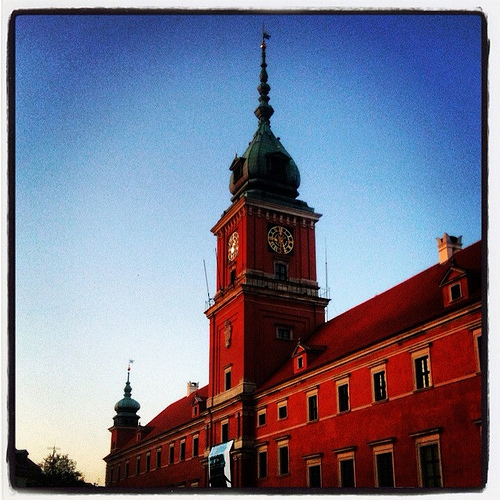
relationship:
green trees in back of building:
[37, 445, 85, 491] [102, 14, 486, 493]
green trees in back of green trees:
[37, 445, 85, 491] [37, 445, 85, 491]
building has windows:
[89, 174, 479, 471] [166, 340, 451, 475]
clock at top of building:
[262, 223, 297, 253] [102, 14, 486, 493]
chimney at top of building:
[413, 225, 475, 270] [102, 14, 486, 493]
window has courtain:
[416, 355, 431, 387] [415, 356, 430, 386]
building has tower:
[102, 14, 486, 493] [204, 26, 329, 403]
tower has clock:
[204, 26, 329, 403] [256, 226, 301, 260]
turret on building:
[249, 18, 281, 132] [102, 14, 486, 493]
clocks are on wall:
[221, 215, 307, 266] [214, 202, 322, 297]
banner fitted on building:
[210, 440, 235, 489] [102, 14, 486, 493]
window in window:
[331, 452, 358, 489] [404, 349, 434, 390]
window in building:
[299, 377, 325, 427] [102, 14, 486, 493]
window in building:
[325, 367, 356, 416] [102, 14, 486, 493]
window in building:
[359, 352, 394, 408] [102, 14, 486, 493]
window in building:
[415, 355, 431, 390] [102, 14, 486, 493]